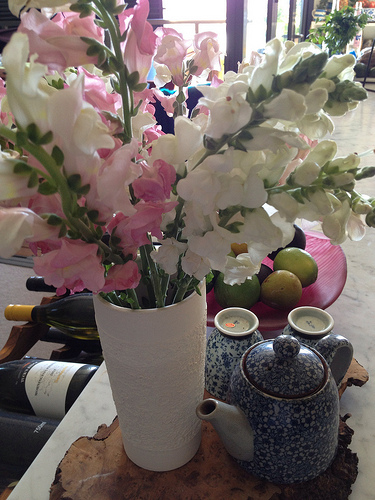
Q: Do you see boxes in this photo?
A: No, there are no boxes.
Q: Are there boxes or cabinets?
A: No, there are no boxes or cabinets.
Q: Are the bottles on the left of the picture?
A: Yes, the bottles are on the left of the image.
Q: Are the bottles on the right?
A: No, the bottles are on the left of the image.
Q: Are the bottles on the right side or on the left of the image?
A: The bottles are on the left of the image.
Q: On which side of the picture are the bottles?
A: The bottles are on the left of the image.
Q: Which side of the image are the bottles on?
A: The bottles are on the left of the image.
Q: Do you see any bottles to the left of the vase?
A: Yes, there are bottles to the left of the vase.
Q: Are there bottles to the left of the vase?
A: Yes, there are bottles to the left of the vase.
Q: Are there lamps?
A: No, there are no lamps.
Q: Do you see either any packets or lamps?
A: No, there are no lamps or packets.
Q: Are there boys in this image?
A: No, there are no boys.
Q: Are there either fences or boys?
A: No, there are no boys or fences.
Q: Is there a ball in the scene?
A: No, there are no balls.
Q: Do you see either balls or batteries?
A: No, there are no balls or batteries.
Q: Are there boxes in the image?
A: No, there are no boxes.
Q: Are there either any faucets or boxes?
A: No, there are no boxes or faucets.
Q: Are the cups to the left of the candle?
A: Yes, the cups are to the left of the candle.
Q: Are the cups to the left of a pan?
A: No, the cups are to the left of the candle.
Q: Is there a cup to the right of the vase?
A: Yes, there are cups to the right of the vase.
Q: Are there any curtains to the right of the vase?
A: No, there are cups to the right of the vase.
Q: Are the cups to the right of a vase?
A: Yes, the cups are to the right of a vase.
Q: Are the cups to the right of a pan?
A: No, the cups are to the right of a vase.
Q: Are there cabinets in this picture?
A: No, there are no cabinets.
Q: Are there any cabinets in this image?
A: No, there are no cabinets.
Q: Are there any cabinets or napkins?
A: No, there are no cabinets or napkins.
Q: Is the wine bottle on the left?
A: Yes, the wine bottle is on the left of the image.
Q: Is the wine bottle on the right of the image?
A: No, the wine bottle is on the left of the image.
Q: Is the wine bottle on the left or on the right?
A: The wine bottle is on the left of the image.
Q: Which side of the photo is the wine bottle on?
A: The wine bottle is on the left of the image.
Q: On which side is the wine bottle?
A: The wine bottle is on the left of the image.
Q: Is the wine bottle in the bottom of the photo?
A: Yes, the wine bottle is in the bottom of the image.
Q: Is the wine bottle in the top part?
A: No, the wine bottle is in the bottom of the image.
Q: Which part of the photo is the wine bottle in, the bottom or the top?
A: The wine bottle is in the bottom of the image.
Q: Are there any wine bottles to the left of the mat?
A: Yes, there is a wine bottle to the left of the mat.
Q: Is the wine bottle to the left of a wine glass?
A: No, the wine bottle is to the left of the mat.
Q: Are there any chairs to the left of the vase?
A: No, there is a wine bottle to the left of the vase.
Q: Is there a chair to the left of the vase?
A: No, there is a wine bottle to the left of the vase.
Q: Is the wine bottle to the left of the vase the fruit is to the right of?
A: Yes, the wine bottle is to the left of the vase.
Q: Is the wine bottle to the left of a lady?
A: No, the wine bottle is to the left of the vase.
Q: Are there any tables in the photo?
A: Yes, there is a table.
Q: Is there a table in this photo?
A: Yes, there is a table.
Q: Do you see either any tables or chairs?
A: Yes, there is a table.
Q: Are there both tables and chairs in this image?
A: No, there is a table but no chairs.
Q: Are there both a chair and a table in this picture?
A: No, there is a table but no chairs.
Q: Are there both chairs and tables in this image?
A: No, there is a table but no chairs.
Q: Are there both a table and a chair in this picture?
A: No, there is a table but no chairs.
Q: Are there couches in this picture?
A: No, there are no couches.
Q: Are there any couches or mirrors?
A: No, there are no couches or mirrors.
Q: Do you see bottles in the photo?
A: Yes, there is a bottle.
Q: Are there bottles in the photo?
A: Yes, there is a bottle.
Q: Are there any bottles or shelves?
A: Yes, there is a bottle.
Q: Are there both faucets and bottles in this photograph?
A: No, there is a bottle but no faucets.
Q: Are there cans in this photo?
A: No, there are no cans.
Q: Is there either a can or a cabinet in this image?
A: No, there are no cans or cabinets.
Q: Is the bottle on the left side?
A: Yes, the bottle is on the left of the image.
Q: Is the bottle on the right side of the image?
A: No, the bottle is on the left of the image.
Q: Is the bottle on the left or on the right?
A: The bottle is on the left of the image.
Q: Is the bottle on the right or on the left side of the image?
A: The bottle is on the left of the image.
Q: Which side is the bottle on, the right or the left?
A: The bottle is on the left of the image.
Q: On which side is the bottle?
A: The bottle is on the left of the image.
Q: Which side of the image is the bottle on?
A: The bottle is on the left of the image.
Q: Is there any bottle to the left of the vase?
A: Yes, there is a bottle to the left of the vase.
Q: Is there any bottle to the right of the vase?
A: No, the bottle is to the left of the vase.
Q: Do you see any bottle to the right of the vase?
A: No, the bottle is to the left of the vase.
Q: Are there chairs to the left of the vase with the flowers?
A: No, there is a bottle to the left of the vase.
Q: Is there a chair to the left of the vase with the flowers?
A: No, there is a bottle to the left of the vase.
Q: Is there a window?
A: Yes, there are windows.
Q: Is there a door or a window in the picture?
A: Yes, there are windows.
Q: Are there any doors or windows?
A: Yes, there are windows.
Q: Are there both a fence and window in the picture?
A: No, there are windows but no fences.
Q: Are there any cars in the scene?
A: No, there are no cars.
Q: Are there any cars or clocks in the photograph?
A: No, there are no cars or clocks.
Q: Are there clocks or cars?
A: No, there are no cars or clocks.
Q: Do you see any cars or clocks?
A: No, there are no cars or clocks.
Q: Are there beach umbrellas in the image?
A: No, there are no beach umbrellas.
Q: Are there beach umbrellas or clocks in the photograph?
A: No, there are no beach umbrellas or clocks.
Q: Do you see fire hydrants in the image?
A: No, there are no fire hydrants.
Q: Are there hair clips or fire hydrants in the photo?
A: No, there are no fire hydrants or hair clips.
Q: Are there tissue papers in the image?
A: No, there are no tissue papers.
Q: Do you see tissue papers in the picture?
A: No, there are no tissue papers.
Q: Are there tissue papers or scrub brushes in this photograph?
A: No, there are no tissue papers or scrub brushes.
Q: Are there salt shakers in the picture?
A: No, there are no salt shakers.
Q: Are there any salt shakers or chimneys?
A: No, there are no salt shakers or chimneys.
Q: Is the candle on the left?
A: No, the candle is on the right of the image.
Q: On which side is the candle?
A: The candle is on the right of the image.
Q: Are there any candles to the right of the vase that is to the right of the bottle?
A: Yes, there is a candle to the right of the vase.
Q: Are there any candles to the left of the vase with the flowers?
A: No, the candle is to the right of the vase.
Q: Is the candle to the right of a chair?
A: No, the candle is to the right of the vase.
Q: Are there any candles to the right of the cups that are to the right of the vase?
A: Yes, there is a candle to the right of the cups.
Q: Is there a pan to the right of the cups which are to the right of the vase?
A: No, there is a candle to the right of the cups.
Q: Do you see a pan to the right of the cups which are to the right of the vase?
A: No, there is a candle to the right of the cups.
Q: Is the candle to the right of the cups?
A: Yes, the candle is to the right of the cups.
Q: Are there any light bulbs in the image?
A: No, there are no light bulbs.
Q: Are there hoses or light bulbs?
A: No, there are no light bulbs or hoses.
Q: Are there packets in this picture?
A: No, there are no packets.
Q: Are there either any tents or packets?
A: No, there are no packets or tents.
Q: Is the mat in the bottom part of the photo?
A: Yes, the mat is in the bottom of the image.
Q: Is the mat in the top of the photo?
A: No, the mat is in the bottom of the image.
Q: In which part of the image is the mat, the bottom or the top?
A: The mat is in the bottom of the image.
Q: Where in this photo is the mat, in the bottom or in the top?
A: The mat is in the bottom of the image.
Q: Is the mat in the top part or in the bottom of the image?
A: The mat is in the bottom of the image.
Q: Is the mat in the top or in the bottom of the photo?
A: The mat is in the bottom of the image.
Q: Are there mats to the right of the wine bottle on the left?
A: Yes, there is a mat to the right of the wine bottle.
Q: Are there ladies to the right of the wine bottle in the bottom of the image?
A: No, there is a mat to the right of the wine bottle.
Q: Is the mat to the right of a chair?
A: No, the mat is to the right of a wine bottle.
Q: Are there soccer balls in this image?
A: No, there are no soccer balls.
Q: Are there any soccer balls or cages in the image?
A: No, there are no soccer balls or cages.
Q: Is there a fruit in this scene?
A: Yes, there is a fruit.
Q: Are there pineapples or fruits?
A: Yes, there is a fruit.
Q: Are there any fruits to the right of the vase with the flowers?
A: Yes, there is a fruit to the right of the vase.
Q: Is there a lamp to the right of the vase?
A: No, there is a fruit to the right of the vase.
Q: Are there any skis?
A: No, there are no skis.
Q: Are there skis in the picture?
A: No, there are no skis.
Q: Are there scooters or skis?
A: No, there are no skis or scooters.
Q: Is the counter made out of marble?
A: Yes, the counter is made of marble.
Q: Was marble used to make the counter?
A: Yes, the counter is made of marble.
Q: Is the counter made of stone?
A: No, the counter is made of marble.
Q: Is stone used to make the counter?
A: No, the counter is made of marble.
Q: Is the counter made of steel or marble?
A: The counter is made of marble.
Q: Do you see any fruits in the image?
A: Yes, there is a fruit.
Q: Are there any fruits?
A: Yes, there is a fruit.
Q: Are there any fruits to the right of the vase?
A: Yes, there is a fruit to the right of the vase.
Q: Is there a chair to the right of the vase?
A: No, there is a fruit to the right of the vase.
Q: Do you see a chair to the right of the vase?
A: No, there is a fruit to the right of the vase.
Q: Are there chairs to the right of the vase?
A: No, there is a fruit to the right of the vase.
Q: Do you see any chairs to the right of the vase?
A: No, there is a fruit to the right of the vase.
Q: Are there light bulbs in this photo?
A: No, there are no light bulbs.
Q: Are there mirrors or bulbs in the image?
A: No, there are no bulbs or mirrors.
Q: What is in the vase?
A: The flowers are in the vase.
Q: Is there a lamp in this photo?
A: No, there are no lamps.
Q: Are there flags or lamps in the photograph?
A: No, there are no lamps or flags.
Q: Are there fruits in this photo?
A: Yes, there is a fruit.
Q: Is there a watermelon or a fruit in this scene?
A: Yes, there is a fruit.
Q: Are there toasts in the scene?
A: No, there are no toasts.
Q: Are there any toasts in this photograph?
A: No, there are no toasts.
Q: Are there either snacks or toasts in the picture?
A: No, there are no toasts or snacks.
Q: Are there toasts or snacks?
A: No, there are no toasts or snacks.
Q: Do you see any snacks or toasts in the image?
A: No, there are no toasts or snacks.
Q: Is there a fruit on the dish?
A: Yes, there is a fruit on the dish.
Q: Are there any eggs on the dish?
A: No, there is a fruit on the dish.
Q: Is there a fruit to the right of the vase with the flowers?
A: Yes, there is a fruit to the right of the vase.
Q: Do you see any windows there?
A: Yes, there is a window.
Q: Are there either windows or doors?
A: Yes, there is a window.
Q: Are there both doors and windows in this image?
A: No, there is a window but no doors.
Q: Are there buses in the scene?
A: No, there are no buses.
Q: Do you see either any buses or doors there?
A: No, there are no buses or doors.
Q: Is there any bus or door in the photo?
A: No, there are no buses or doors.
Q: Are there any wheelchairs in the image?
A: No, there are no wheelchairs.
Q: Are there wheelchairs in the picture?
A: No, there are no wheelchairs.